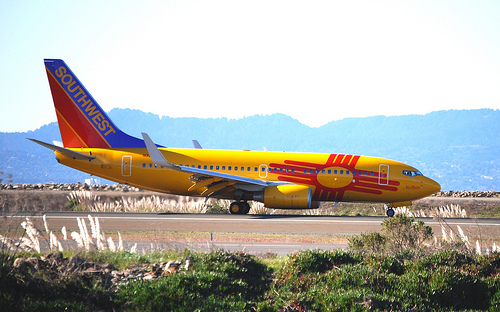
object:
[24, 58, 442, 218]
plane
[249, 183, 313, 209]
engine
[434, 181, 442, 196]
nose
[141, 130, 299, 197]
wing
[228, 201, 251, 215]
wheel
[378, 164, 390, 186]
door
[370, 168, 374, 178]
window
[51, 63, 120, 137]
symbol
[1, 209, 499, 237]
runway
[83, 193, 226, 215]
plant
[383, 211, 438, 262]
shrub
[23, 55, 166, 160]
tail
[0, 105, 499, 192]
mountain